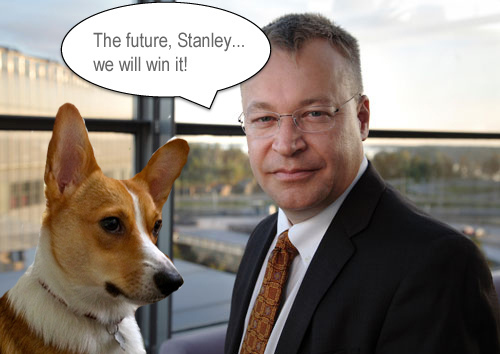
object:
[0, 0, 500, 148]
sky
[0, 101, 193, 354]
dog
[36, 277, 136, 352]
collar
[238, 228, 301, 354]
tie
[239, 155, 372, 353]
white shirt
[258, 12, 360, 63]
hair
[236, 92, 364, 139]
glasses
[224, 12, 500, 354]
man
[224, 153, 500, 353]
suit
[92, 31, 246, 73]
letter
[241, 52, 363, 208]
face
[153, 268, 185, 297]
nose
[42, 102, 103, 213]
dog's ear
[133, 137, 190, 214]
dog's ear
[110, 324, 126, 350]
tags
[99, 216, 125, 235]
eye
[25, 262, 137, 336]
neck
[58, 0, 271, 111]
bubble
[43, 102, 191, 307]
head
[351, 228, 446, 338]
suit jacket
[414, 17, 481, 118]
clouds